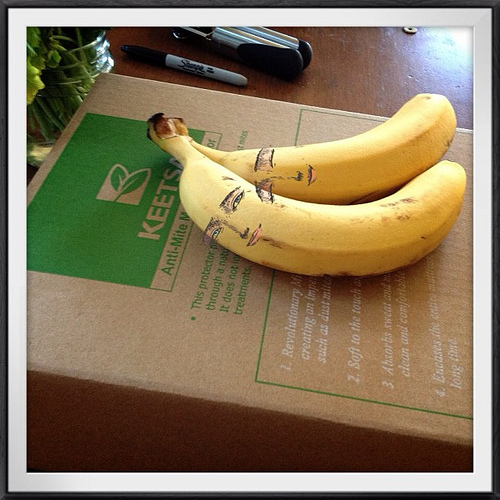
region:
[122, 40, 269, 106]
black sharpie medium point permanent marker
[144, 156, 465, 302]
one banana with a face that has open eyes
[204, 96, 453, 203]
one banana with a face that has closed eyes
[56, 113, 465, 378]
two bananas laying a brown box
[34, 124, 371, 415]
brown box with green ink on it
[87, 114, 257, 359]
brown box with the letter k on it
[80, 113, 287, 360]
brown box with the letter e on it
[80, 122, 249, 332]
brown box with the letter t on it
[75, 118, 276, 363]
brown box with the letter s on it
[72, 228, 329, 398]
brown box with the work anti on it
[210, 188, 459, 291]
the bananas are ripe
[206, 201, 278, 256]
there is a face on the banana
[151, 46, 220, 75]
the marker is on the table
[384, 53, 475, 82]
the table is brown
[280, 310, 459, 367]
the writing is white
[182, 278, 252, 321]
the writing is blue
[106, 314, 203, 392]
the table is brown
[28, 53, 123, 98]
the glass has plats in it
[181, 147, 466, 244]
the bananas are yellow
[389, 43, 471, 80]
there is reflection on the table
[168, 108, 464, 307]
the two bannas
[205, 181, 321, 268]
bannas with faces on it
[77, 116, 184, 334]
the box with the green sign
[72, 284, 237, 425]
a brown box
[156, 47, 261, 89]
a sharpie on the table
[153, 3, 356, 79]
a stapler on the table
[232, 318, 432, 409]
writing on the box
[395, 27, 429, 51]
a button on the table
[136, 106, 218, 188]
the stem of the bannana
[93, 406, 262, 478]
the side of the brown box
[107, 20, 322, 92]
Sharpie and other pens on desk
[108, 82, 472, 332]
Two bananas with faces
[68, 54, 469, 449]
Two bananas on a box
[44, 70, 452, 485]
Desk with box and bananas on it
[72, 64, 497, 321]
Two unpeeled bananas with faces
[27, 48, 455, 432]
Box with green print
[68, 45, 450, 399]
Bananas with sharpie drawn faces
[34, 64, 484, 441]
Brown box two bananas on the box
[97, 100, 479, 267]
Bananas with full faces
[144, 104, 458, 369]
Banana with female face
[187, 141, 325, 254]
two bananas have faces painted on them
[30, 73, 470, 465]
two bananas are sitting on a box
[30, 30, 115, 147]
greens are in a glass of water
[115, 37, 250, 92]
a black and gray pen is on the table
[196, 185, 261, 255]
the eyes are open on the banana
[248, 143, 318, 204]
the eyes are closed on the banana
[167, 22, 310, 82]
an object is sitting next to the pen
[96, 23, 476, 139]
the table is wooden next to the box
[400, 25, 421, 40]
a button is lying on the desk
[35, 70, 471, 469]
the cardboard box has green and white print